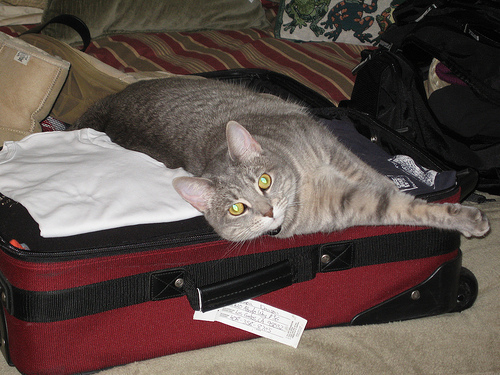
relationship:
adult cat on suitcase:
[62, 73, 490, 266] [33, 236, 483, 337]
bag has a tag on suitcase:
[196, 285, 308, 352] [39, 223, 495, 354]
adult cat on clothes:
[62, 73, 490, 266] [0, 125, 216, 239]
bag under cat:
[0, 123, 477, 374] [115, 67, 389, 260]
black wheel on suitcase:
[454, 269, 477, 312] [15, 242, 446, 333]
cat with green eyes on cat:
[226, 200, 246, 218] [142, 80, 362, 252]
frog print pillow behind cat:
[279, 1, 384, 47] [164, 51, 408, 317]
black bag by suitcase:
[352, 12, 499, 196] [33, 236, 483, 337]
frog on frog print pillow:
[325, 4, 381, 47] [279, 1, 384, 47]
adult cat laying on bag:
[62, 70, 480, 279] [0, 123, 477, 374]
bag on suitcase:
[0, 123, 477, 374] [0, 181, 475, 373]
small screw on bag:
[318, 249, 338, 268] [0, 123, 477, 374]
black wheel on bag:
[454, 269, 488, 316] [0, 123, 477, 374]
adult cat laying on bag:
[62, 73, 490, 266] [0, 123, 477, 374]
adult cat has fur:
[62, 73, 490, 266] [97, 70, 490, 244]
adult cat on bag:
[62, 73, 490, 266] [0, 123, 477, 374]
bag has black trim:
[0, 123, 477, 374] [348, 228, 456, 259]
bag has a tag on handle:
[196, 285, 308, 352] [178, 251, 348, 312]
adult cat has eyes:
[62, 73, 490, 266] [231, 175, 274, 220]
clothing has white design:
[317, 116, 472, 190] [384, 169, 417, 195]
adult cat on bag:
[62, 73, 490, 266] [0, 145, 462, 325]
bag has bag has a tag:
[9, 241, 490, 365] [196, 285, 308, 352]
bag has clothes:
[0, 123, 477, 374] [22, 135, 217, 265]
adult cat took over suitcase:
[62, 73, 490, 266] [18, 261, 418, 349]